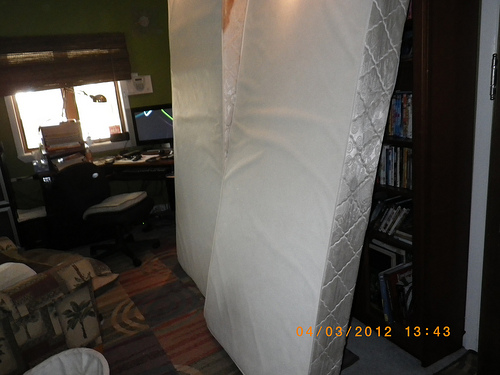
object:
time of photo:
[402, 324, 455, 341]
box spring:
[200, 1, 411, 375]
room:
[0, 1, 500, 374]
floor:
[60, 218, 488, 371]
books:
[381, 261, 413, 325]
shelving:
[350, 1, 479, 365]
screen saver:
[135, 107, 175, 148]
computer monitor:
[129, 103, 177, 155]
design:
[63, 297, 93, 343]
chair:
[0, 241, 102, 375]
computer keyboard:
[114, 154, 159, 165]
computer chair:
[55, 160, 157, 268]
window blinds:
[1, 31, 134, 96]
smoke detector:
[135, 11, 151, 29]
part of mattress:
[167, 1, 219, 296]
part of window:
[3, 89, 79, 156]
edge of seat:
[83, 191, 156, 231]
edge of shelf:
[408, 3, 480, 368]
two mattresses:
[161, 0, 413, 375]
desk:
[91, 155, 174, 218]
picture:
[0, 0, 499, 375]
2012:
[350, 324, 393, 340]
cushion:
[82, 186, 148, 216]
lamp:
[109, 132, 132, 158]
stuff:
[87, 144, 178, 172]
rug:
[74, 229, 362, 374]